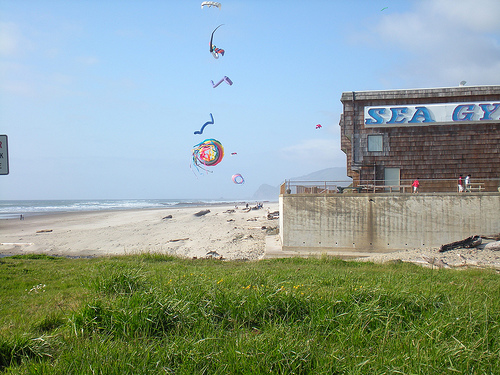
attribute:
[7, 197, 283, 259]
beach — long, tan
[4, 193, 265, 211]
ocean — grey, white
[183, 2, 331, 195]
kites — multicolored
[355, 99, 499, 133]
sea gy — white, black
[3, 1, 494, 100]
sky — partly cloudy, blue, white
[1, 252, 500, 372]
grassy strip — green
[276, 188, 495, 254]
wall — concrete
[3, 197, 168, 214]
breaking waves — white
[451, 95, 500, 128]
sign — large